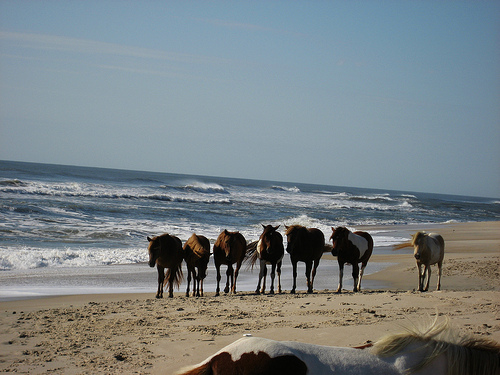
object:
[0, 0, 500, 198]
sky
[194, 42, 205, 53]
clouds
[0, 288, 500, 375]
beach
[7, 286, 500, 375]
sand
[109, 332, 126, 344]
tracks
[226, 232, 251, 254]
fur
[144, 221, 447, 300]
animal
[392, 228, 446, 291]
horse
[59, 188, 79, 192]
waves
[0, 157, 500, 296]
ocean